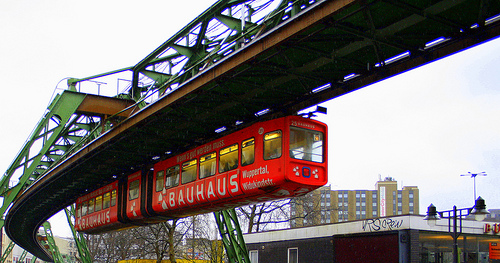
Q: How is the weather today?
A: It is overcast.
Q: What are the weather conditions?
A: It is overcast.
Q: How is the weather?
A: It is overcast.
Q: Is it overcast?
A: Yes, it is overcast.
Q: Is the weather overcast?
A: Yes, it is overcast.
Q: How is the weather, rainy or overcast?
A: It is overcast.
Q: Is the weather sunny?
A: No, it is overcast.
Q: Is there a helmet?
A: No, there are no helmets.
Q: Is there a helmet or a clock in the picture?
A: No, there are no helmets or clocks.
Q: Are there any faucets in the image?
A: No, there are no faucets.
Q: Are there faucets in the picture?
A: No, there are no faucets.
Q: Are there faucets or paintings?
A: No, there are no faucets or paintings.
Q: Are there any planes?
A: No, there are no planes.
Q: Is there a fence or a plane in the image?
A: No, there are no airplanes or fences.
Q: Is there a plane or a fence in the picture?
A: No, there are no airplanes or fences.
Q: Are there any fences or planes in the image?
A: No, there are no planes or fences.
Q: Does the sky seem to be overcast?
A: Yes, the sky is overcast.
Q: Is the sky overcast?
A: Yes, the sky is overcast.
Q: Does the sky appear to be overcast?
A: Yes, the sky is overcast.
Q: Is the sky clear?
A: No, the sky is overcast.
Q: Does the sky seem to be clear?
A: No, the sky is overcast.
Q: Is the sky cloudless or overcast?
A: The sky is overcast.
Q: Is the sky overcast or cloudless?
A: The sky is overcast.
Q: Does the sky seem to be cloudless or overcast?
A: The sky is overcast.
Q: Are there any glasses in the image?
A: No, there are no glasses.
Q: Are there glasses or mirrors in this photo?
A: No, there are no glasses or mirrors.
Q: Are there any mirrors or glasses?
A: No, there are no glasses or mirrors.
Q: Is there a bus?
A: No, there are no buses.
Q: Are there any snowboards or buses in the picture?
A: No, there are no buses or snowboards.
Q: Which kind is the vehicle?
A: The vehicle is a car.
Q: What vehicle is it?
A: The vehicle is a car.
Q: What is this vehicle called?
A: This is a car.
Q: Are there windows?
A: Yes, there is a window.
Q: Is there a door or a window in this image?
A: Yes, there is a window.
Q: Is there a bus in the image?
A: No, there are no buses.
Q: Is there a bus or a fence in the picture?
A: No, there are no buses or fences.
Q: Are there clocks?
A: No, there are no clocks.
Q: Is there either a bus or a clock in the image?
A: No, there are no clocks or buses.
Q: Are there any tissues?
A: No, there are no tissues.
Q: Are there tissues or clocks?
A: No, there are no tissues or clocks.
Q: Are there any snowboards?
A: No, there are no snowboards.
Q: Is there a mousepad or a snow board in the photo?
A: No, there are no snowboards or mouse pads.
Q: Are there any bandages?
A: No, there are no bandages.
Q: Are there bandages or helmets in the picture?
A: No, there are no bandages or helmets.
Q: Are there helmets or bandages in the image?
A: No, there are no bandages or helmets.